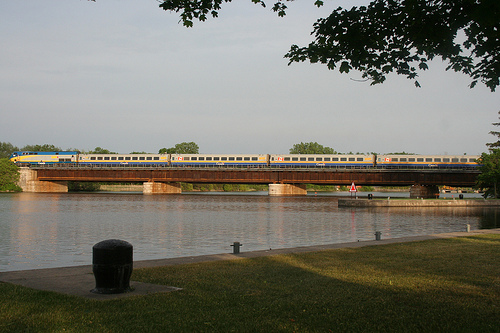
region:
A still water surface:
[283, 205, 343, 252]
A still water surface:
[147, 187, 219, 220]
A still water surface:
[8, 214, 69, 266]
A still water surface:
[394, 204, 462, 224]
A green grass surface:
[279, 295, 402, 329]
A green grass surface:
[4, 285, 80, 327]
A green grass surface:
[368, 247, 470, 317]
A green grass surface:
[187, 258, 290, 294]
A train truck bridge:
[39, 143, 474, 180]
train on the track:
[8, 138, 498, 175]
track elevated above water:
[11, 160, 498, 178]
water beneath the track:
[6, 192, 408, 233]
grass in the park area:
[185, 268, 478, 321]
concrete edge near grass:
[254, 244, 299, 255]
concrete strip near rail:
[338, 194, 498, 210]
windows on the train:
[93, 153, 128, 160]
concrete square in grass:
[28, 276, 173, 302]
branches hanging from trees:
[301, 14, 498, 99]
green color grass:
[306, 272, 399, 319]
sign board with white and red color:
[350, 180, 357, 192]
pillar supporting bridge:
[268, 184, 306, 195]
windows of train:
[290, 158, 305, 162]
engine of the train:
[8, 151, 75, 161]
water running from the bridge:
[76, 192, 254, 229]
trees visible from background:
[290, 143, 334, 153]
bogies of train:
[80, 152, 376, 164]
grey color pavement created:
[178, 254, 252, 261]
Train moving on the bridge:
[5, 150, 497, 169]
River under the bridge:
[3, 190, 498, 271]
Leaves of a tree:
[155, 0, 495, 95]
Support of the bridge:
[265, 180, 307, 195]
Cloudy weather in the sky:
[0, 0, 495, 150]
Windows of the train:
[86, 155, 156, 160]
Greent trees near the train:
[0, 137, 335, 152]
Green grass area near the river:
[0, 230, 495, 327]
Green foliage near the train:
[0, 155, 20, 185]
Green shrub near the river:
[186, 181, 268, 192]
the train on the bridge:
[10, 144, 487, 181]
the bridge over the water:
[10, 160, 489, 210]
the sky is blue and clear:
[4, 17, 278, 127]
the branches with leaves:
[296, 9, 499, 71]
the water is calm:
[6, 191, 353, 268]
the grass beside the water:
[19, 251, 498, 331]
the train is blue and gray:
[11, 145, 493, 165]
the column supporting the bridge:
[139, 170, 180, 197]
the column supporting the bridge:
[263, 180, 313, 200]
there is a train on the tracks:
[6, 132, 498, 221]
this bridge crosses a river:
[9, 139, 495, 219]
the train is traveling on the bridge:
[10, 142, 497, 220]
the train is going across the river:
[7, 140, 498, 224]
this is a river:
[9, 186, 494, 278]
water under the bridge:
[67, 183, 497, 197]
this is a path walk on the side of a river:
[31, 223, 498, 328]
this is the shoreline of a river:
[6, 213, 493, 328]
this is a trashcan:
[80, 208, 161, 315]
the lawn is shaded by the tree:
[12, 218, 488, 326]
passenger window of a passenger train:
[102, 155, 109, 160]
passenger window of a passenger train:
[95, 155, 100, 160]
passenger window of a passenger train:
[111, 155, 116, 160]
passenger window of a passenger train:
[153, 154, 160, 161]